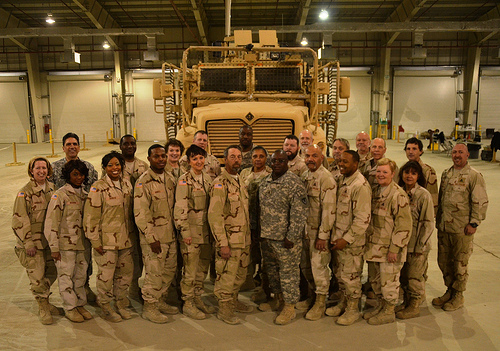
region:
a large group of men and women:
[18, 109, 497, 335]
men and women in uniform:
[0, 124, 488, 318]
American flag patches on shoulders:
[19, 180, 230, 211]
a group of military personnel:
[14, 113, 498, 331]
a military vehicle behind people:
[131, 24, 376, 213]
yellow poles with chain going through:
[1, 118, 121, 164]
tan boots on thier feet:
[26, 281, 477, 341]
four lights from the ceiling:
[38, 6, 383, 71]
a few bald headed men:
[293, 123, 392, 175]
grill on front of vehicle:
[199, 110, 312, 170]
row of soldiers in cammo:
[14, 124, 486, 333]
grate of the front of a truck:
[182, 108, 307, 161]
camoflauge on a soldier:
[217, 174, 244, 242]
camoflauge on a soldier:
[264, 176, 305, 263]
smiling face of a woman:
[27, 150, 53, 185]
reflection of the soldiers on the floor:
[338, 326, 496, 349]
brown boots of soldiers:
[324, 292, 406, 328]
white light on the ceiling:
[310, 8, 339, 28]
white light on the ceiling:
[101, 34, 112, 53]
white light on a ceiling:
[40, 13, 59, 28]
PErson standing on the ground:
[3, 148, 63, 340]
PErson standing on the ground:
[435, 115, 480, 313]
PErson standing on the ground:
[396, 165, 439, 310]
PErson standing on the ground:
[370, 155, 407, 323]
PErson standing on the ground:
[332, 141, 364, 332]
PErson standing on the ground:
[297, 143, 344, 323]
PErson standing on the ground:
[258, 140, 322, 333]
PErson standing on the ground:
[200, 138, 252, 333]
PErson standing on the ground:
[161, 136, 224, 336]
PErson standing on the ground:
[142, 122, 183, 331]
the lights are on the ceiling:
[284, 0, 351, 51]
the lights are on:
[292, 0, 343, 55]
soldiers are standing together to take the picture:
[18, 122, 485, 323]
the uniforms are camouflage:
[43, 135, 482, 314]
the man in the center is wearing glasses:
[257, 135, 300, 191]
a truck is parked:
[147, 5, 359, 179]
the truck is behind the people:
[84, 2, 355, 169]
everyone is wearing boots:
[20, 273, 476, 340]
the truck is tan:
[161, 2, 347, 172]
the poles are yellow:
[0, 111, 123, 168]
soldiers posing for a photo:
[8, 120, 495, 328]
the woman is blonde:
[365, 144, 410, 331]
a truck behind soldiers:
[6, 7, 496, 336]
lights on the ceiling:
[36, 6, 341, 58]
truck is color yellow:
[136, 22, 358, 154]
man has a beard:
[207, 142, 262, 327]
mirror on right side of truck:
[332, 66, 356, 105]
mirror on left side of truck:
[143, 73, 170, 122]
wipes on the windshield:
[189, 56, 306, 98]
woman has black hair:
[173, 141, 222, 198]